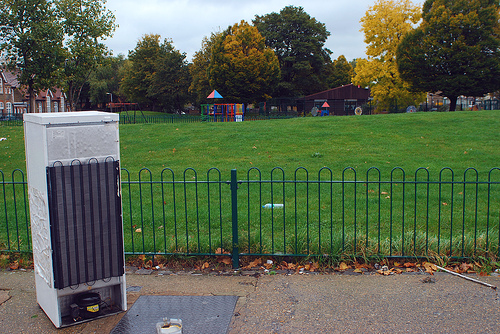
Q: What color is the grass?
A: The grass is green.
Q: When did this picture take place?
A: It took place in the day time.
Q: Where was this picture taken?
A: At a playground.